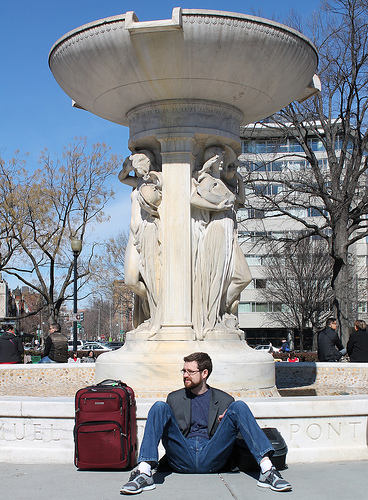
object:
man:
[116, 349, 294, 494]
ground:
[34, 464, 69, 499]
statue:
[112, 87, 254, 349]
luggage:
[72, 378, 139, 472]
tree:
[275, 140, 367, 318]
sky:
[4, 32, 46, 108]